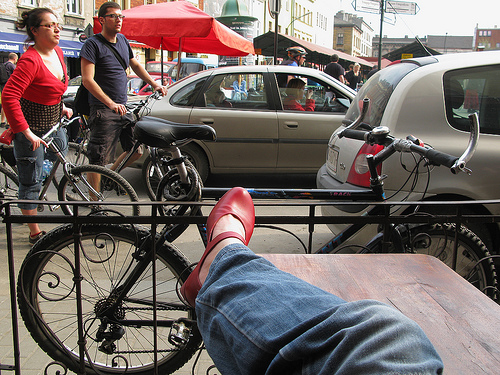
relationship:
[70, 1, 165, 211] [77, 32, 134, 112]
man wearing shirt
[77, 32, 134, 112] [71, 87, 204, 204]
shirt standing with bicycle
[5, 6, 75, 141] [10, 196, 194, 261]
woman standing on sidewalk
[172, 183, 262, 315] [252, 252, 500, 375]
shoe resting on wood table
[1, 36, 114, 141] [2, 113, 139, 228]
shirt standing with bicycle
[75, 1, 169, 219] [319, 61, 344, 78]
man wearing shirt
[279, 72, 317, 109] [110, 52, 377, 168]
woman sitting in car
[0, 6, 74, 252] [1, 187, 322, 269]
woman standing in street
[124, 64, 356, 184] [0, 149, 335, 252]
car sitting in street